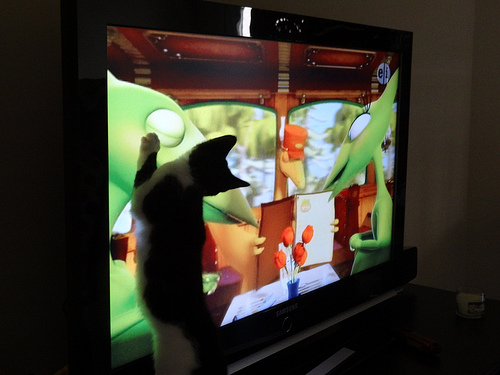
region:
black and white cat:
[107, 111, 257, 372]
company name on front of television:
[270, 295, 307, 315]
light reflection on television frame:
[232, 7, 263, 39]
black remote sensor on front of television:
[278, 312, 301, 337]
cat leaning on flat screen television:
[60, 4, 449, 367]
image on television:
[250, 38, 392, 258]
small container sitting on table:
[445, 269, 495, 334]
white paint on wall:
[413, 35, 466, 211]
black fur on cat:
[158, 225, 200, 276]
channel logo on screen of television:
[367, 57, 395, 87]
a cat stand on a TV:
[119, 118, 262, 373]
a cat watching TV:
[106, 32, 407, 362]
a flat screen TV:
[71, 15, 437, 365]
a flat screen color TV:
[81, 19, 439, 363]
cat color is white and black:
[123, 113, 255, 373]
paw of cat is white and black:
[121, 112, 161, 177]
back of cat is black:
[153, 175, 225, 350]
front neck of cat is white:
[153, 142, 195, 173]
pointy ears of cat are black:
[211, 125, 258, 196]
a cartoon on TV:
[123, 52, 407, 333]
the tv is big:
[27, 4, 422, 315]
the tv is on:
[44, 1, 437, 336]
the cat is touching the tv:
[125, 125, 250, 370]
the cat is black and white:
[127, 110, 254, 365]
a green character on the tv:
[317, 55, 389, 245]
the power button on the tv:
[265, 294, 300, 335]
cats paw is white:
[132, 128, 164, 157]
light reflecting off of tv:
[198, 0, 278, 48]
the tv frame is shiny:
[157, 0, 364, 42]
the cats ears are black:
[205, 125, 255, 207]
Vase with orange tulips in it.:
[272, 223, 316, 305]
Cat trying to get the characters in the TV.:
[135, 128, 255, 373]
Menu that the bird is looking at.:
[255, 189, 335, 269]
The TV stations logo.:
[371, 60, 396, 86]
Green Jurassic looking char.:
[319, 65, 404, 283]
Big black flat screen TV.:
[2, 0, 426, 364]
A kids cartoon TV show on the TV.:
[104, 25, 399, 367]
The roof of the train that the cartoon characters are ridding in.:
[105, 27, 399, 109]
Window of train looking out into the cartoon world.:
[180, 102, 400, 263]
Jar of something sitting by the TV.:
[453, 287, 487, 322]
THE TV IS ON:
[103, 20, 406, 373]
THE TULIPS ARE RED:
[268, 220, 320, 276]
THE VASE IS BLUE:
[283, 275, 301, 304]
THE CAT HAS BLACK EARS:
[213, 128, 254, 195]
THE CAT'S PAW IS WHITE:
[132, 123, 164, 158]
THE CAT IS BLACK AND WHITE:
[126, 125, 258, 373]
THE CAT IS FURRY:
[123, 122, 257, 373]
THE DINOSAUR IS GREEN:
[306, 70, 403, 275]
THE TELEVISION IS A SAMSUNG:
[258, 297, 305, 318]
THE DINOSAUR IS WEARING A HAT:
[277, 120, 312, 162]